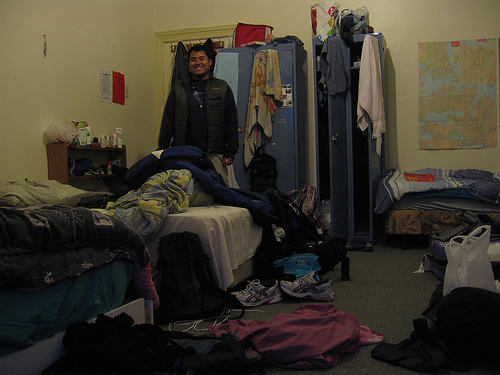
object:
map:
[417, 38, 498, 150]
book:
[403, 172, 436, 182]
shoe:
[230, 268, 336, 307]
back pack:
[151, 231, 245, 323]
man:
[158, 44, 240, 189]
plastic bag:
[443, 225, 498, 298]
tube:
[107, 161, 112, 175]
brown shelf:
[47, 143, 127, 185]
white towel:
[357, 34, 387, 157]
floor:
[155, 239, 500, 375]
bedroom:
[0, 0, 499, 375]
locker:
[218, 32, 387, 245]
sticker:
[281, 83, 292, 107]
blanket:
[0, 259, 134, 354]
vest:
[171, 76, 227, 152]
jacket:
[158, 73, 239, 161]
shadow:
[280, 347, 360, 371]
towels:
[320, 36, 351, 96]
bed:
[383, 194, 500, 249]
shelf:
[69, 173, 117, 179]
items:
[45, 120, 123, 149]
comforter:
[374, 168, 500, 215]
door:
[365, 35, 382, 242]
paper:
[113, 71, 125, 105]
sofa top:
[0, 206, 159, 355]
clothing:
[244, 48, 283, 168]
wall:
[0, 1, 500, 186]